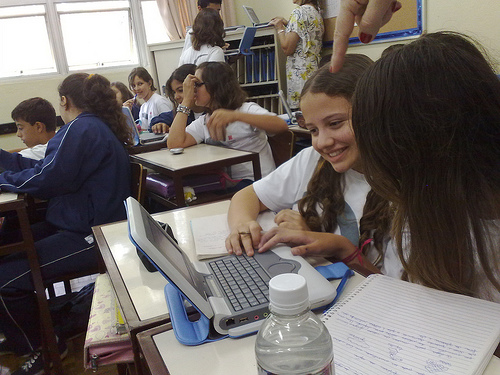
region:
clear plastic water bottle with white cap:
[254, 274, 331, 374]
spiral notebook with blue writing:
[316, 273, 498, 374]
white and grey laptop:
[124, 194, 334, 345]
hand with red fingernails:
[328, 0, 402, 72]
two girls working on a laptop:
[126, 31, 497, 350]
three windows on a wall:
[0, 1, 171, 81]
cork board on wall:
[316, 1, 425, 51]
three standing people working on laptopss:
[173, 2, 324, 114]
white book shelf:
[148, 27, 286, 116]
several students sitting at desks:
[1, 63, 288, 370]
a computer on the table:
[73, 114, 457, 371]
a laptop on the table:
[129, 193, 361, 357]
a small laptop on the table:
[53, 158, 382, 372]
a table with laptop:
[124, 139, 361, 343]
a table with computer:
[117, 176, 385, 364]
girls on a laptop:
[208, 123, 483, 328]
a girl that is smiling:
[283, 58, 428, 204]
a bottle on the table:
[257, 261, 422, 374]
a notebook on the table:
[299, 240, 477, 327]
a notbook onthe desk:
[273, 209, 425, 357]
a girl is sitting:
[172, 69, 287, 183]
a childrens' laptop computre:
[121, 193, 331, 335]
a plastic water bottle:
[257, 274, 336, 374]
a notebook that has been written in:
[312, 273, 495, 374]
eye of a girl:
[327, 113, 346, 128]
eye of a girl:
[309, 124, 318, 137]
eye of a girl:
[136, 81, 142, 87]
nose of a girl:
[317, 125, 334, 149]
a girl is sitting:
[8, 72, 125, 367]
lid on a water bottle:
[267, 270, 309, 314]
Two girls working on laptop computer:
[120, 30, 499, 350]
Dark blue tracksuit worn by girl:
[0, 111, 135, 354]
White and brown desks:
[80, 191, 499, 373]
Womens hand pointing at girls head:
[323, 2, 400, 76]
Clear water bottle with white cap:
[252, 273, 332, 372]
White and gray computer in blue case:
[101, 193, 359, 348]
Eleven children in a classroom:
[1, 3, 499, 373]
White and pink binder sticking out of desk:
[79, 273, 144, 373]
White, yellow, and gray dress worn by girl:
[281, 3, 331, 108]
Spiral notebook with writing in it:
[303, 265, 499, 371]